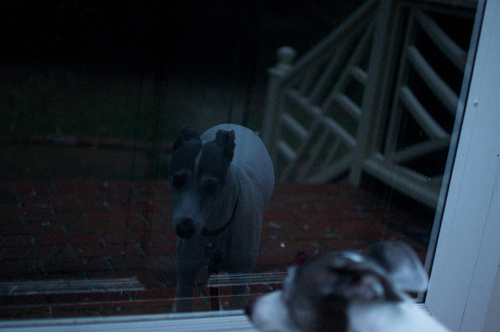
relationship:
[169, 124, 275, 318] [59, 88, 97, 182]
reflection of dog on window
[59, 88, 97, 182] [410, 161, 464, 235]
window on door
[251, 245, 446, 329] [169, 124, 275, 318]
dog looking at reflection of dog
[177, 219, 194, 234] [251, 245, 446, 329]
nose on dog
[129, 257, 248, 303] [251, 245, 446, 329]
legs of dog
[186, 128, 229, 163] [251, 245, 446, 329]
ears attached to dog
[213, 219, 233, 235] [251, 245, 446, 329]
collar on dog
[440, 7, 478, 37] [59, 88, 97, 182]
frame of window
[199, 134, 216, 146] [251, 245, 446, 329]
head of dog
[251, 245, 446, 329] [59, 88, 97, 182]
dog looking into window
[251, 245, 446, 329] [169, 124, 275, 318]
dog looking reflection of dog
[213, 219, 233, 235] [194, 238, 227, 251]
collar has tags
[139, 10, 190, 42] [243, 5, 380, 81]
reflection of room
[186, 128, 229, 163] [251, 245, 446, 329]
ears of dog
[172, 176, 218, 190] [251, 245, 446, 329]
eyes of dog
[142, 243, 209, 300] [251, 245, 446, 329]
leg on dog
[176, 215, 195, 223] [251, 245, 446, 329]
snout of dog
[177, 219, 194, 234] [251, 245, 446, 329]
nose of dog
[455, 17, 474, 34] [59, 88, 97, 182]
pane of window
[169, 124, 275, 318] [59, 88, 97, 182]
reflection of dog in window